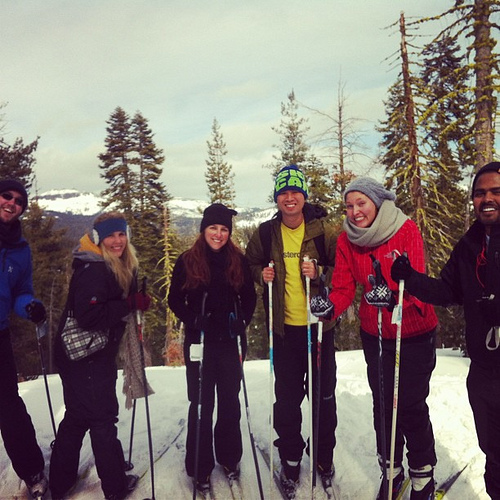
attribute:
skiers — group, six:
[3, 164, 495, 497]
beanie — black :
[200, 203, 235, 235]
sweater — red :
[334, 219, 442, 339]